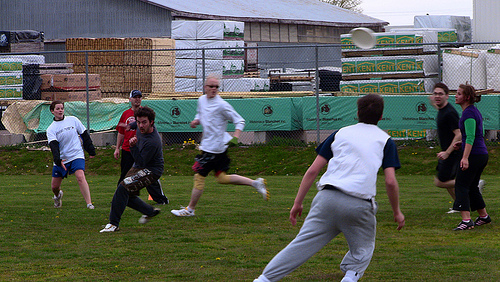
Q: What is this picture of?
A: It is a picture of some people playing frisbee.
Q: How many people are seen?
A: Seven.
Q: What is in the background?
A: A warehouse yard with stacked containers and big cartons.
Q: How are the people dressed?
A: They are informally dressed in sports-clothes.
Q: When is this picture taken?
A: Daytime, probably in the evening.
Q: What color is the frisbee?
A: White.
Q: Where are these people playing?
A: On a fenced ground with grass on it.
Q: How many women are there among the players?
A: One.